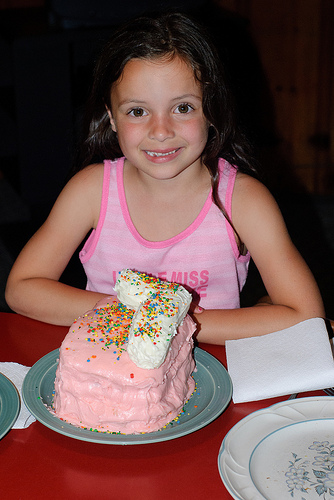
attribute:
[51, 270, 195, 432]
frost — pink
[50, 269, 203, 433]
cake — pink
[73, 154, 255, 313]
tank top — pink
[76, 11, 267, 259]
dark hair — long, very dark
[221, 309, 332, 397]
napkin — white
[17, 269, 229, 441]
cake — pink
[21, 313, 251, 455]
plate — green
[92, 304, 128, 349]
sprinkles — rainbow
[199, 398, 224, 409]
plate — blue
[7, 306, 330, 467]
table — dark orange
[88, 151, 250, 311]
tanktop — pink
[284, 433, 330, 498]
decoration — blue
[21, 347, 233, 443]
plate — blue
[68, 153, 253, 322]
shirt — pink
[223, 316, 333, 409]
napkin — white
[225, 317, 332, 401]
napkin — white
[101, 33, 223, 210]
girl — smiling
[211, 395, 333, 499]
plate — white, empty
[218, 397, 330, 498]
plate — white, wavy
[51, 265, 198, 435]
birthday cake — pink, frosted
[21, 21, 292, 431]
girl — young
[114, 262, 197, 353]
small cake — white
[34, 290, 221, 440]
larger cake — large, pink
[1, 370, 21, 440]
plate — empty, blue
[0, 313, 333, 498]
table — red, shiny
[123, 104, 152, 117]
eye — brown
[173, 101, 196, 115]
eye — brown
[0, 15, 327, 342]
girl — young, long, dark brown